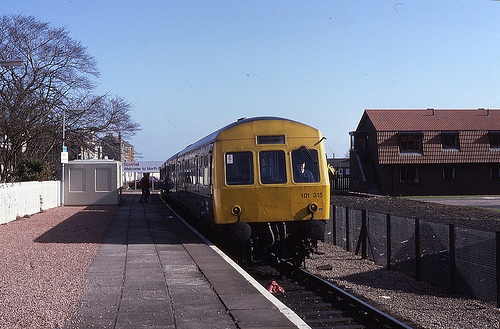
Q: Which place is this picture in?
A: It is at the train station.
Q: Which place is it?
A: It is a train station.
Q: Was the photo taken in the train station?
A: Yes, it was taken in the train station.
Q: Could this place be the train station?
A: Yes, it is the train station.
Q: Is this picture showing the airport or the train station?
A: It is showing the train station.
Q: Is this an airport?
A: No, it is a train station.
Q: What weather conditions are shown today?
A: It is clear.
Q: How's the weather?
A: It is clear.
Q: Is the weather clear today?
A: Yes, it is clear.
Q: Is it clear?
A: Yes, it is clear.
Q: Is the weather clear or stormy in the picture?
A: It is clear.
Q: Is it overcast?
A: No, it is clear.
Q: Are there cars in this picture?
A: No, there are no cars.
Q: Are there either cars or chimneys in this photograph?
A: No, there are no cars or chimneys.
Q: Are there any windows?
A: Yes, there is a window.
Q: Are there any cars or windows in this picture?
A: Yes, there is a window.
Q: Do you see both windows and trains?
A: Yes, there are both a window and a train.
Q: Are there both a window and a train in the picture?
A: Yes, there are both a window and a train.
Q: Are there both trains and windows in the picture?
A: Yes, there are both a window and a train.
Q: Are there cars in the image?
A: No, there are no cars.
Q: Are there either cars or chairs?
A: No, there are no cars or chairs.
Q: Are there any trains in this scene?
A: Yes, there is a train.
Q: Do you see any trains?
A: Yes, there is a train.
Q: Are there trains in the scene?
A: Yes, there is a train.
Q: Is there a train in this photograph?
A: Yes, there is a train.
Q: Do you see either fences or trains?
A: Yes, there is a train.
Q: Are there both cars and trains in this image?
A: No, there is a train but no cars.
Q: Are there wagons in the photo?
A: No, there are no wagons.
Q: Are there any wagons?
A: No, there are no wagons.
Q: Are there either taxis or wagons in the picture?
A: No, there are no wagons or taxis.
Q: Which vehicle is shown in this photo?
A: The vehicle is a train.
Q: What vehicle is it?
A: The vehicle is a train.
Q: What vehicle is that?
A: This is a train.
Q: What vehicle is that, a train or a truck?
A: This is a train.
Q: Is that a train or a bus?
A: That is a train.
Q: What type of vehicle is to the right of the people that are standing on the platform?
A: The vehicle is a train.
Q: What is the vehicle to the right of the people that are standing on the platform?
A: The vehicle is a train.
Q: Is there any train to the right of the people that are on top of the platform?
A: Yes, there is a train to the right of the people.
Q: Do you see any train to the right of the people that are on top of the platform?
A: Yes, there is a train to the right of the people.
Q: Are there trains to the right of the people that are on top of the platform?
A: Yes, there is a train to the right of the people.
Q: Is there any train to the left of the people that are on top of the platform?
A: No, the train is to the right of the people.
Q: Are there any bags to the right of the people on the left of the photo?
A: No, there is a train to the right of the people.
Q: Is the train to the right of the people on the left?
A: Yes, the train is to the right of the people.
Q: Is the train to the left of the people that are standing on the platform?
A: No, the train is to the right of the people.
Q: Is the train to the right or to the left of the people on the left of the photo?
A: The train is to the right of the people.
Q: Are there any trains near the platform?
A: Yes, there is a train near the platform.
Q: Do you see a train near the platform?
A: Yes, there is a train near the platform.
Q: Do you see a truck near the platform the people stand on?
A: No, there is a train near the platform.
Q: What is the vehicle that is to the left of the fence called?
A: The vehicle is a train.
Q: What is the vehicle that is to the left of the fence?
A: The vehicle is a train.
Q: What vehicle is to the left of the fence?
A: The vehicle is a train.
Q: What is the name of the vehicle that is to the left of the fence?
A: The vehicle is a train.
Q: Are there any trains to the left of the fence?
A: Yes, there is a train to the left of the fence.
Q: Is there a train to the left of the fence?
A: Yes, there is a train to the left of the fence.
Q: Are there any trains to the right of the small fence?
A: No, the train is to the left of the fence.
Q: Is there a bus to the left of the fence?
A: No, there is a train to the left of the fence.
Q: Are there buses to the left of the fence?
A: No, there is a train to the left of the fence.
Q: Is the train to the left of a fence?
A: Yes, the train is to the left of a fence.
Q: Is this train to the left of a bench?
A: No, the train is to the left of a fence.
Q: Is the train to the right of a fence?
A: No, the train is to the left of a fence.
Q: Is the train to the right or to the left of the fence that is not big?
A: The train is to the left of the fence.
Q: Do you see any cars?
A: No, there are no cars.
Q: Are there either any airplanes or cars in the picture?
A: No, there are no cars or airplanes.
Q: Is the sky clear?
A: Yes, the sky is clear.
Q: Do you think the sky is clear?
A: Yes, the sky is clear.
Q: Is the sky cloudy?
A: No, the sky is clear.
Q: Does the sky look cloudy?
A: No, the sky is clear.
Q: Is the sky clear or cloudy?
A: The sky is clear.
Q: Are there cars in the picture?
A: No, there are no cars.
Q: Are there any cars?
A: No, there are no cars.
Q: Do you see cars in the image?
A: No, there are no cars.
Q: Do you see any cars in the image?
A: No, there are no cars.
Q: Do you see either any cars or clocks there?
A: No, there are no cars or clocks.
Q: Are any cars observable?
A: No, there are no cars.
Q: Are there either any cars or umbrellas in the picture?
A: No, there are no cars or umbrellas.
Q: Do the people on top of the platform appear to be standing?
A: Yes, the people are standing.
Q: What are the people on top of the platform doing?
A: The people are standing.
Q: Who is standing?
A: The people are standing.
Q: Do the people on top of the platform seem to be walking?
A: No, the people are standing.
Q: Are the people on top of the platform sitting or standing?
A: The people are standing.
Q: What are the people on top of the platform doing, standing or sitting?
A: The people are standing.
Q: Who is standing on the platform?
A: The people are standing on the platform.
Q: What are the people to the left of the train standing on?
A: The people are standing on the platform.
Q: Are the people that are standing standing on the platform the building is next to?
A: Yes, the people are standing on the platform.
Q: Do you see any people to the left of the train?
A: Yes, there are people to the left of the train.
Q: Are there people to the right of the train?
A: No, the people are to the left of the train.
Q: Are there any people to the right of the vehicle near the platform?
A: No, the people are to the left of the train.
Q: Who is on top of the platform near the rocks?
A: The people are on top of the platform.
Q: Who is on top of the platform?
A: The people are on top of the platform.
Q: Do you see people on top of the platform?
A: Yes, there are people on top of the platform.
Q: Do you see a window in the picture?
A: Yes, there is a window.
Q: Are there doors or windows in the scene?
A: Yes, there is a window.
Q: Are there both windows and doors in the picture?
A: No, there is a window but no doors.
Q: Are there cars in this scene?
A: No, there are no cars.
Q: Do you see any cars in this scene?
A: No, there are no cars.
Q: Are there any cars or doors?
A: No, there are no cars or doors.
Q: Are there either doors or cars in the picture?
A: No, there are no cars or doors.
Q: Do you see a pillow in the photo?
A: No, there are no pillows.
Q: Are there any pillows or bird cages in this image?
A: No, there are no pillows or bird cages.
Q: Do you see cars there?
A: No, there are no cars.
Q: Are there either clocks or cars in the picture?
A: No, there are no cars or clocks.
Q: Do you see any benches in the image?
A: No, there are no benches.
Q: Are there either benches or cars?
A: No, there are no benches or cars.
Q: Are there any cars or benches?
A: No, there are no benches or cars.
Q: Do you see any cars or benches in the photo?
A: No, there are no benches or cars.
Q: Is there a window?
A: Yes, there is a window.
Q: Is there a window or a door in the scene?
A: Yes, there is a window.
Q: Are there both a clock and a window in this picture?
A: No, there is a window but no clocks.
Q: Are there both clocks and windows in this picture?
A: No, there is a window but no clocks.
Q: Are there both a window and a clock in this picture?
A: No, there is a window but no clocks.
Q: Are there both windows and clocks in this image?
A: No, there is a window but no clocks.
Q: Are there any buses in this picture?
A: No, there are no buses.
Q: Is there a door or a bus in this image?
A: No, there are no buses or doors.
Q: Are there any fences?
A: Yes, there is a fence.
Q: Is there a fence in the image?
A: Yes, there is a fence.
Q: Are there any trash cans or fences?
A: Yes, there is a fence.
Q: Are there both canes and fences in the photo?
A: No, there is a fence but no canes.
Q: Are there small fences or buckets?
A: Yes, there is a small fence.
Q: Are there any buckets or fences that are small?
A: Yes, the fence is small.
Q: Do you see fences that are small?
A: Yes, there is a small fence.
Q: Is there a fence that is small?
A: Yes, there is a fence that is small.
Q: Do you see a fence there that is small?
A: Yes, there is a fence that is small.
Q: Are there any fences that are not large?
A: Yes, there is a small fence.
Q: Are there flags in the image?
A: No, there are no flags.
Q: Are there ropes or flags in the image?
A: No, there are no flags or ropes.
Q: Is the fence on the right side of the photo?
A: Yes, the fence is on the right of the image.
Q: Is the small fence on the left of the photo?
A: No, the fence is on the right of the image.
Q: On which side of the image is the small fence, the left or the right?
A: The fence is on the right of the image.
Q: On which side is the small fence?
A: The fence is on the right of the image.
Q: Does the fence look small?
A: Yes, the fence is small.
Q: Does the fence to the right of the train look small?
A: Yes, the fence is small.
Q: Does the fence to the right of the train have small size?
A: Yes, the fence is small.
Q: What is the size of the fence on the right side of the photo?
A: The fence is small.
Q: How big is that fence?
A: The fence is small.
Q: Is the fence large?
A: No, the fence is small.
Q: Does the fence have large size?
A: No, the fence is small.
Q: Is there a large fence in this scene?
A: No, there is a fence but it is small.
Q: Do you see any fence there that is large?
A: No, there is a fence but it is small.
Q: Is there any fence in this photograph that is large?
A: No, there is a fence but it is small.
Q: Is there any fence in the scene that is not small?
A: No, there is a fence but it is small.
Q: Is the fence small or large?
A: The fence is small.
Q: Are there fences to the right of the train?
A: Yes, there is a fence to the right of the train.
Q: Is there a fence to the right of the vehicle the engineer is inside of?
A: Yes, there is a fence to the right of the train.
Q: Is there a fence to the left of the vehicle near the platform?
A: No, the fence is to the right of the train.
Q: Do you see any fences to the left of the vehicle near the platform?
A: No, the fence is to the right of the train.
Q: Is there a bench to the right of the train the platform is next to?
A: No, there is a fence to the right of the train.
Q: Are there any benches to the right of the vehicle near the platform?
A: No, there is a fence to the right of the train.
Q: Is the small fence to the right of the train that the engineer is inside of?
A: Yes, the fence is to the right of the train.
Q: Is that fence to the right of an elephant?
A: No, the fence is to the right of the train.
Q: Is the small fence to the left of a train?
A: No, the fence is to the right of a train.